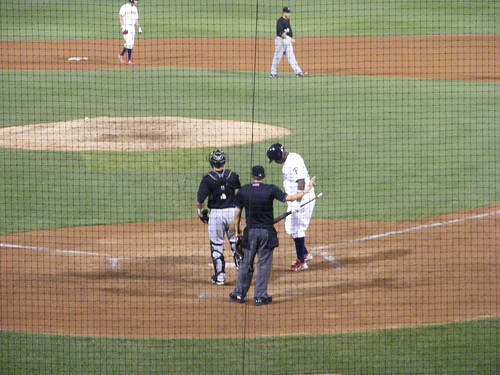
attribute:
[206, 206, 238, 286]
pants — gray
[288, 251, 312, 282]
shoes — red, white, man's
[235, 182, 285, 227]
shirt — black, man's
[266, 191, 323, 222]
bat — brown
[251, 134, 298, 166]
helmet — black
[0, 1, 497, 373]
grass — green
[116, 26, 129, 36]
glove — baseball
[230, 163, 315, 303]
umpire — at a game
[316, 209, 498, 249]
chalk line — white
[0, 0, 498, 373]
field — baseball